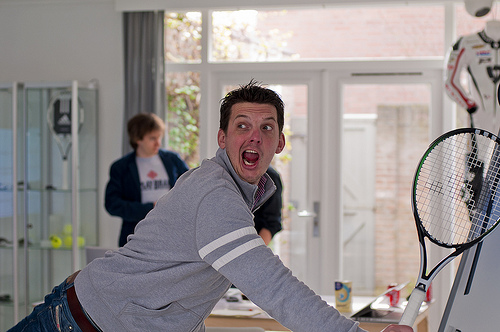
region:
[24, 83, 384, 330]
man wearing gray shirt with white stripes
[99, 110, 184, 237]
man standing beside window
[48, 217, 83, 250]
stack of tennis balls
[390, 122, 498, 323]
black and white tennis racket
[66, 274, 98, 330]
brown belt man is wearing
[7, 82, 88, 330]
glass shelfs against the wall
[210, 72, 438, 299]
glass doors with white frames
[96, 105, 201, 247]
hipster standing near a doorway.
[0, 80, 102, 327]
A metal and glass shelf.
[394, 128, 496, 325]
A tennis racket in a hand.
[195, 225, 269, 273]
White lines on a gray t shirt.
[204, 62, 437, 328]
A large glass and wood doorway.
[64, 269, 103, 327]
A brown belt around a waist.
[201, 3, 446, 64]
A large window above a doorway.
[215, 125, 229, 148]
A right human ear.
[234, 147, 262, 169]
the mouth is open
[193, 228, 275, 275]
the stripes are white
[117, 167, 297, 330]
stripes on the sweater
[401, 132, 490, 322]
handle on the racket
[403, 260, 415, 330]
the handle is white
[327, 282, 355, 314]
carton on the table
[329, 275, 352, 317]
the carton is yellow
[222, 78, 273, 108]
the hair is dark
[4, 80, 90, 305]
items in the case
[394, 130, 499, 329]
Tennis racket in man's hand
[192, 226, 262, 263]
White stripes on gray shirt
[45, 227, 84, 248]
Pile of tennis balls on a shelf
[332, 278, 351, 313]
Yellow box with blue swirl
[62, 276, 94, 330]
Brown belt on man's pants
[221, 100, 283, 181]
Man's face with wide open mouth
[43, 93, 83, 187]
Tennis racket hanging on a shelf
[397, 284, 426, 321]
White grip on tennis racket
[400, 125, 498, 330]
tennis racket in a man's hand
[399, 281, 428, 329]
white handle on a tennis racket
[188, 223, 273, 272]
white stripes on a grey sleeve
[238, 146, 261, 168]
man's open mouth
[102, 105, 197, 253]
man in the background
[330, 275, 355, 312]
yellow container on a counter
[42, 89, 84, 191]
tennis racket in a glass case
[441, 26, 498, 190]
white race outfit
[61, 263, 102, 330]
a man's brown belt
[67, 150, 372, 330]
grey zippered jacket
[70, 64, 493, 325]
brunette man holding tennis racket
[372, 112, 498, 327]
black and white tennis racket